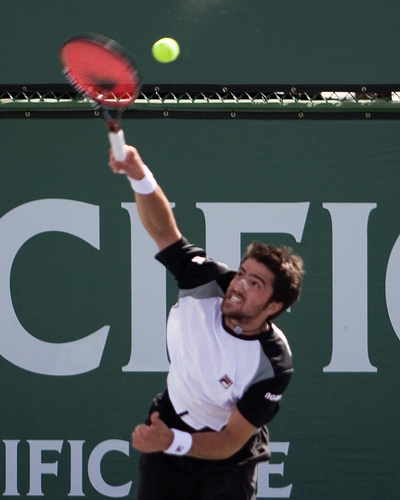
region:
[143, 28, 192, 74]
bright green tennis ball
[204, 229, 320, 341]
man gritting his teeth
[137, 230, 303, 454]
black and white tee shirt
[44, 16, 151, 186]
red and white tennis racket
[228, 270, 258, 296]
breathing strip on nose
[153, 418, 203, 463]
bright white wrist band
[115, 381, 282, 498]
plain black gym shorts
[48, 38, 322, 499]
man hitting tennis ball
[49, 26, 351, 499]
man swinging tennis racket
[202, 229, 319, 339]
man with lots of stubble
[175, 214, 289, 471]
a man playing tennis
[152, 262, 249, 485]
a man playing tennis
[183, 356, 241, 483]
a man playing tennis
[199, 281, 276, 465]
a man playing tennis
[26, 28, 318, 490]
a tennis player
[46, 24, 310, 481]
a tennis player trying to hit a ball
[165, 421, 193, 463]
a white wristband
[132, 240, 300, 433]
man wearing a white and black shirt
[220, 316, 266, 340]
man wearing a necklace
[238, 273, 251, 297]
man with a band-aid on his nose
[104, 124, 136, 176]
white handle of a tennis racket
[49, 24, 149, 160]
a tennis racket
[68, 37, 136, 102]
red strings of a tennis racket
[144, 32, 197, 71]
a yellow ball flying in the air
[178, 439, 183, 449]
the risk band is white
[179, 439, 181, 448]
the risk band is white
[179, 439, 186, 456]
the risk band is white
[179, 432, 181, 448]
the risk band is white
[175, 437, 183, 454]
the risk band is white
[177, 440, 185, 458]
the risk band is white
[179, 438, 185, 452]
the risk band is white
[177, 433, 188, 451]
the risk band is white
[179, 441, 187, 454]
the risk band is white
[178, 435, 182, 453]
the risk band is white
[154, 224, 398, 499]
a man playing tennis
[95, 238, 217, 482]
a man playing tennis